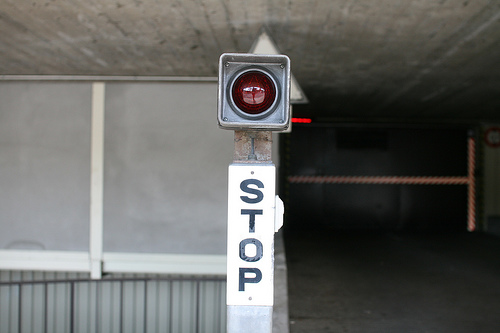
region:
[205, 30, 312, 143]
this is a light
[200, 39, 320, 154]
outer part is square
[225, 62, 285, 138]
the light is red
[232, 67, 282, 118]
reflection on the light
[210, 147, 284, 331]
this is a post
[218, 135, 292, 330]
white sign on post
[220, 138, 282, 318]
black writing on post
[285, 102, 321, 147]
red illumination in the background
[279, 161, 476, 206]
a orange striped line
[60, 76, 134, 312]
white line in background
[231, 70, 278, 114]
Round red light on a post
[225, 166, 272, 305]
White sign on a post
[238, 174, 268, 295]
Black letters on a post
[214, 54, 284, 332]
Post with a light on it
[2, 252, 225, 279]
White frame on building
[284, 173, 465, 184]
A horizontal striped pole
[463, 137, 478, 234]
A vertical striped pole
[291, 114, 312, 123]
Bright red light against wall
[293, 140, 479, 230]
A metal pole barrier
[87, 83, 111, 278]
A vertical white stripe on a wall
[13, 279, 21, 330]
Small iron fence post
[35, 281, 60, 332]
Small iron fence post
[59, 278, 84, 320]
Small iron fence post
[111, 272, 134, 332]
Small iron fence post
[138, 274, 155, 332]
Small iron fence post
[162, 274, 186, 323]
Small iron fence post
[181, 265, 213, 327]
Small iron fence post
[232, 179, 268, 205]
Black letter on white post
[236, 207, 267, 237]
Black letter on white post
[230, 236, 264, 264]
Black letter on white post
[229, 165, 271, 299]
a black and white sign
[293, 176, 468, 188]
a red nd white bar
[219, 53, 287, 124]
a red light on a post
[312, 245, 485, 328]
a concrete road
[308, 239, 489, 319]
a gray concrete road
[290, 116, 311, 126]
a red neon light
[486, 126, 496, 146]
a red and white sign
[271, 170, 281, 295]
paint peeling off a post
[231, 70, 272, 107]
a reflection in a light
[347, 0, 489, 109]
a concrete gray ceiling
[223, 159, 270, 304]
The verticle white stop sign.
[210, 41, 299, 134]
The camera-like traffic light.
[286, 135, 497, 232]
A twisted steel T shaped rod.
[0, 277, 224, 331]
The thin metal railing.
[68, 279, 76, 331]
The thin metal spokes of the railing.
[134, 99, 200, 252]
The grey wall of the building.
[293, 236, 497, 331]
The dark concrete flooring in the area.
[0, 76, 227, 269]
The white paneled area.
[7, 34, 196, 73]
The ceiling of the area with grooves.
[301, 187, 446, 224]
The wall in the background.